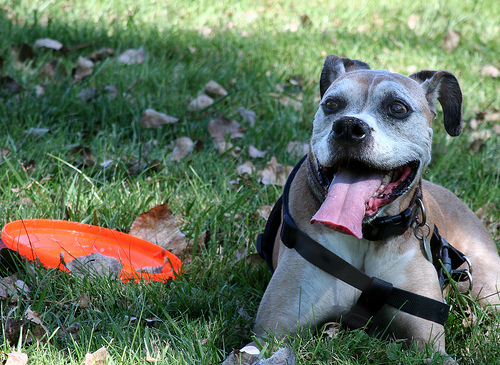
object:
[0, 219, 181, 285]
frisbee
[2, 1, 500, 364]
grass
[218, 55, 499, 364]
dog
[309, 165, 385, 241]
tongue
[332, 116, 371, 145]
nose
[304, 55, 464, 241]
head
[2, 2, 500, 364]
photo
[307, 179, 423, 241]
collar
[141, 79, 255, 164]
leaves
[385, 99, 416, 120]
eye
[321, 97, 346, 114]
eye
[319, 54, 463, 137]
ears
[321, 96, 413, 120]
eyes